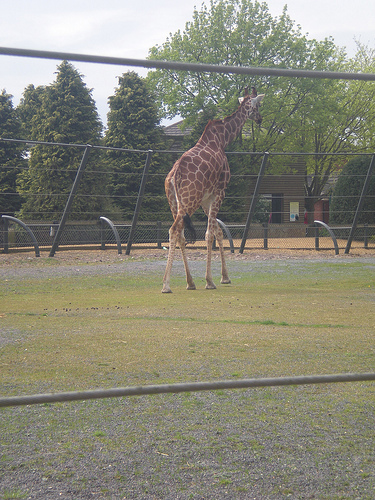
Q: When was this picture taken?
A: Daytime.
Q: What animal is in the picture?
A: A Giraffe.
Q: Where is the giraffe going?
A: Toward the fence.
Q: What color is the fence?
A: Dark green.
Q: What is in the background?
A: Trees and a building.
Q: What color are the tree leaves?
A: Green.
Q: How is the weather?
A: Sunny.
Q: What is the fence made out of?
A: Metal.